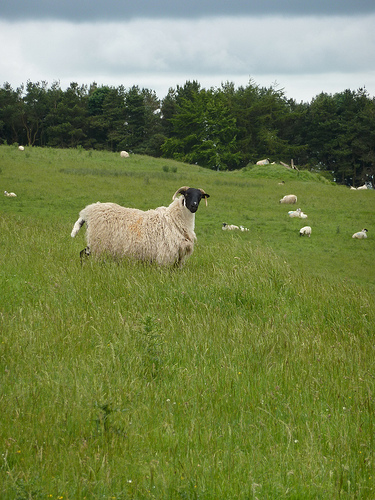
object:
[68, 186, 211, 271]
sheep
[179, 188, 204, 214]
face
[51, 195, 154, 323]
grass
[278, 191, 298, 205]
sheep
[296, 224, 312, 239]
sheep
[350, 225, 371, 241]
sheep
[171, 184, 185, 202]
horn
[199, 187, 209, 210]
horn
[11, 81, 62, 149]
trees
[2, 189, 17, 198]
lamb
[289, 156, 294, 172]
post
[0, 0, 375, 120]
sky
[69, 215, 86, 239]
tail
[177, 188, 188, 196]
ear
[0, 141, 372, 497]
hill